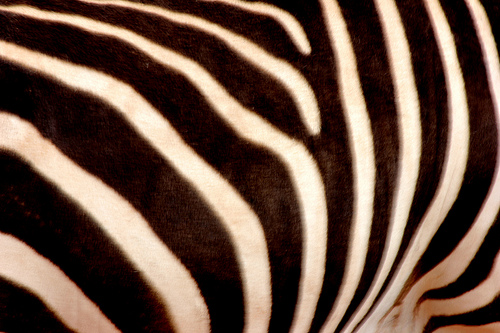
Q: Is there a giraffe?
A: No, there are no giraffes.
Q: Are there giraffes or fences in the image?
A: No, there are no giraffes or fences.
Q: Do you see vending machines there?
A: No, there are no vending machines.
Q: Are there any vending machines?
A: No, there are no vending machines.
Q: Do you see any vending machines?
A: No, there are no vending machines.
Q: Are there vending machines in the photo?
A: No, there are no vending machines.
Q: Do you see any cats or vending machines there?
A: No, there are no vending machines or cats.